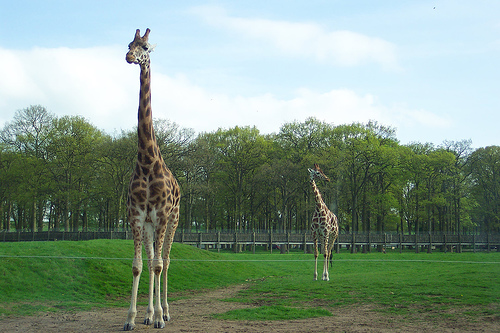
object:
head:
[124, 25, 154, 65]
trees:
[397, 140, 440, 249]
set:
[367, 180, 453, 250]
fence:
[0, 231, 498, 254]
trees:
[186, 122, 275, 251]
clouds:
[2, 47, 281, 141]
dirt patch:
[167, 275, 260, 329]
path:
[72, 279, 269, 330]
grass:
[2, 237, 500, 330]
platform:
[182, 231, 500, 254]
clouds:
[13, 41, 383, 130]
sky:
[0, 0, 500, 160]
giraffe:
[295, 157, 342, 283]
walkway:
[180, 223, 497, 254]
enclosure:
[4, 212, 498, 329]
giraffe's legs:
[124, 204, 147, 330]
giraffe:
[118, 20, 185, 330]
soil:
[0, 280, 494, 333]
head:
[302, 161, 331, 183]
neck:
[308, 179, 328, 211]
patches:
[0, 283, 497, 331]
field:
[0, 239, 496, 331]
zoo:
[2, 227, 497, 331]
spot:
[148, 159, 164, 179]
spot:
[145, 172, 155, 182]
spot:
[138, 167, 151, 177]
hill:
[0, 238, 298, 312]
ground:
[0, 251, 500, 331]